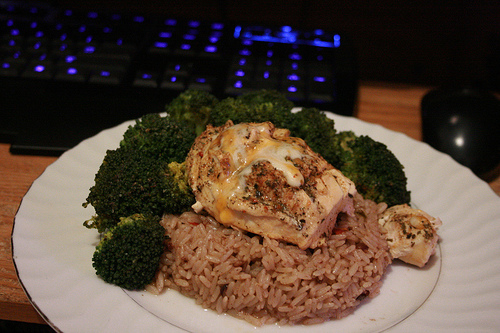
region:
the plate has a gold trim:
[12, 103, 497, 330]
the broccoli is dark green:
[93, 97, 410, 286]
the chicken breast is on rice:
[193, 123, 442, 266]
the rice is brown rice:
[163, 201, 390, 323]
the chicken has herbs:
[186, 124, 443, 269]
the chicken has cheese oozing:
[218, 131, 310, 193]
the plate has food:
[13, 101, 498, 331]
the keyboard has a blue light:
[1, 3, 353, 109]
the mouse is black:
[424, 90, 496, 183]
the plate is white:
[12, 105, 497, 331]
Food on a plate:
[12, 85, 499, 328]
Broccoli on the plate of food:
[91, 216, 168, 291]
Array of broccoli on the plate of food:
[81, 86, 412, 290]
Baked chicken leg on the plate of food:
[179, 122, 441, 266]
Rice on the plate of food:
[136, 193, 390, 325]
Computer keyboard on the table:
[0, 4, 357, 154]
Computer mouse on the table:
[419, 82, 499, 180]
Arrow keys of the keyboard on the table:
[132, 58, 215, 92]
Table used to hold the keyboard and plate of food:
[1, 77, 498, 323]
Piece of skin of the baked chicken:
[231, 159, 307, 224]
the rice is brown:
[182, 220, 294, 314]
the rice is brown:
[216, 248, 378, 331]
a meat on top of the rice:
[142, 92, 402, 302]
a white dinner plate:
[11, 105, 498, 331]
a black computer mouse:
[418, 79, 498, 182]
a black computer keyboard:
[0, 0, 361, 157]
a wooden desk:
[0, 83, 499, 324]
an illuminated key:
[56, 63, 88, 80]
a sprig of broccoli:
[92, 212, 167, 290]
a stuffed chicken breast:
[184, 120, 356, 247]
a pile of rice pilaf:
[145, 198, 390, 325]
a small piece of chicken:
[378, 203, 441, 268]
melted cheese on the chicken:
[225, 123, 305, 187]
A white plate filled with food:
[13, 104, 498, 331]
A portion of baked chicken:
[183, 125, 345, 236]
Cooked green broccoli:
[97, 94, 409, 285]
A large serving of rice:
[163, 207, 389, 317]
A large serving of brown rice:
[155, 196, 382, 321]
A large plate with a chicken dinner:
[13, 108, 496, 332]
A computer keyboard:
[0, 3, 358, 138]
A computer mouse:
[417, 85, 497, 182]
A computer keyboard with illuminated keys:
[0, 4, 357, 144]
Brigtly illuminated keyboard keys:
[0, 0, 344, 93]